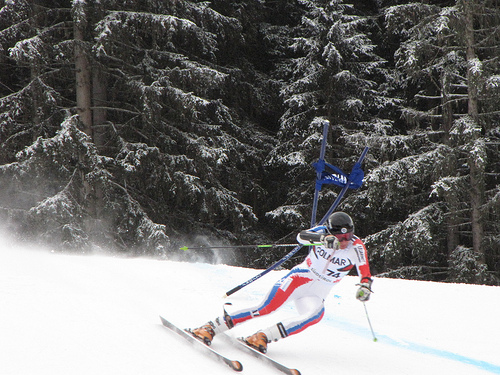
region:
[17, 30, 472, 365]
picture taken outside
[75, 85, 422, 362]
picture taken during the day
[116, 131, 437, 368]
a down hill skier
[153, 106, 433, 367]
a professional skier sking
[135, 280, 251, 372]
the man has two skies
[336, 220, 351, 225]
the man has a ski helmet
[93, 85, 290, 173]
the trees are covered with snow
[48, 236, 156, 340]
the snow is very white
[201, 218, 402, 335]
the man wears blue, white and red clothing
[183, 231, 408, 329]
the man holds two ski poles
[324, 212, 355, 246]
the skier is wearing a helmet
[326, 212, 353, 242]
the helmet is black in color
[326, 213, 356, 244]
the helmet is shiny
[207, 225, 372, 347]
the skier is wearing an outfit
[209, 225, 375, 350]
the outfit is white red and blue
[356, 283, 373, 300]
the skier is wearing gloves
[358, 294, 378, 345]
the skier is holding ski poles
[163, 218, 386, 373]
the skier is goind down the hill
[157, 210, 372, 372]
the skier is at an angle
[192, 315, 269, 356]
the skier is wearing boots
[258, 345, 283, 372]
part of a board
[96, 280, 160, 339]
part of a splash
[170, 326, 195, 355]
part of a board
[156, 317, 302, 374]
A pair of silver skis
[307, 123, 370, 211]
Blue flagpole to ski around during slalom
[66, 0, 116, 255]
Trunks of two Douglas firs on far left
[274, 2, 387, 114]
Snow-covered top of evergreen tree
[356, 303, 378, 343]
Ski propeller on skiier's left arm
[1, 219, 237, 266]
Snow powder kicked up from skiing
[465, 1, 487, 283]
Trunk of a Douglas fir on the far right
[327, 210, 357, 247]
Black ski helmet with red-tinted visor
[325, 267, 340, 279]
The number 74 in black text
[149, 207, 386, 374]
Slalom skiier passing a blue flag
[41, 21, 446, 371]
The skier is going down the slopes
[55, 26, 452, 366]
A skier is in a race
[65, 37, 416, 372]
A skier is moving fast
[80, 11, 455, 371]
A person is in the snow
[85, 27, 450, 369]
A person is wearing skis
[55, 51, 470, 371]
A person is wearing a helmet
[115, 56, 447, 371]
A person is holding ski poles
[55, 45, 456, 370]
The person is wearing goggles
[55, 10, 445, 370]
A skier is close to some trees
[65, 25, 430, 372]
A skier is hitting top speed